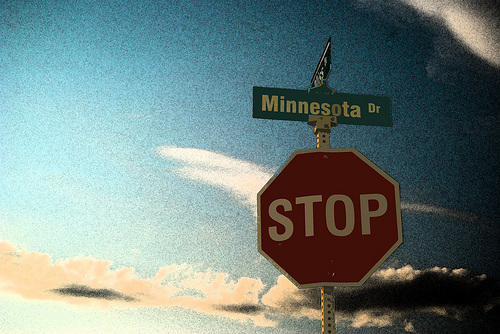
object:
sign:
[256, 148, 404, 290]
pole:
[319, 286, 336, 334]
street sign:
[253, 86, 394, 127]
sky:
[96, 19, 183, 75]